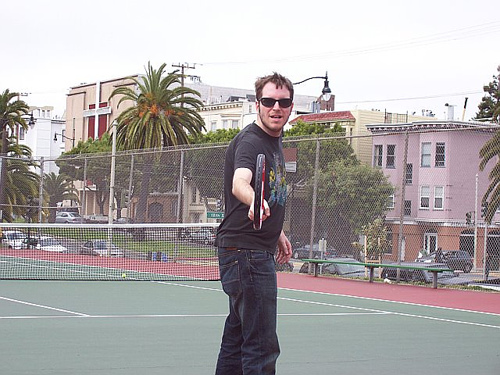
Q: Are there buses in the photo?
A: No, there are no buses.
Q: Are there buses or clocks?
A: No, there are no buses or clocks.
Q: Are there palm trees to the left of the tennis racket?
A: Yes, there is a palm tree to the left of the tennis racket.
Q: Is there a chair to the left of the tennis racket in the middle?
A: No, there is a palm tree to the left of the tennis racket.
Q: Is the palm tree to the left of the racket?
A: Yes, the palm tree is to the left of the racket.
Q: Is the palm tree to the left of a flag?
A: No, the palm tree is to the left of the racket.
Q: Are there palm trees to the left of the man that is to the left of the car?
A: Yes, there is a palm tree to the left of the man.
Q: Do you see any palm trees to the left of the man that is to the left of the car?
A: Yes, there is a palm tree to the left of the man.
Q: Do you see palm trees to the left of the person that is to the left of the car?
A: Yes, there is a palm tree to the left of the man.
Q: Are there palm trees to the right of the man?
A: No, the palm tree is to the left of the man.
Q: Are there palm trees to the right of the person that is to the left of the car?
A: No, the palm tree is to the left of the man.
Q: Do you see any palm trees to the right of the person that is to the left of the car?
A: No, the palm tree is to the left of the man.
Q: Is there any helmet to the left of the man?
A: No, there is a palm tree to the left of the man.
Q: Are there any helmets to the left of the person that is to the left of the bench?
A: No, there is a palm tree to the left of the man.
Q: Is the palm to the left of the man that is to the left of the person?
A: Yes, the palm is to the left of the man.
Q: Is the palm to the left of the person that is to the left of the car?
A: Yes, the palm is to the left of the man.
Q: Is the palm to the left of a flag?
A: No, the palm is to the left of the man.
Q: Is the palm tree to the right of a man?
A: No, the palm tree is to the left of a man.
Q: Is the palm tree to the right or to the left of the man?
A: The palm tree is to the left of the man.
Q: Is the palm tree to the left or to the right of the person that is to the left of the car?
A: The palm tree is to the left of the man.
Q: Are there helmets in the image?
A: No, there are no helmets.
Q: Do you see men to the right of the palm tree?
A: Yes, there is a man to the right of the palm tree.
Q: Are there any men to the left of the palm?
A: No, the man is to the right of the palm.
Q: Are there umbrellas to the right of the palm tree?
A: No, there is a man to the right of the palm tree.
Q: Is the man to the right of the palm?
A: Yes, the man is to the right of the palm.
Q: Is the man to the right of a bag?
A: No, the man is to the right of the palm.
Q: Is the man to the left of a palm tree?
A: No, the man is to the right of a palm tree.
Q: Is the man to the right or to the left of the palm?
A: The man is to the right of the palm.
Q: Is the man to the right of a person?
A: No, the man is to the left of a person.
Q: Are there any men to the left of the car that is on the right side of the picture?
A: Yes, there is a man to the left of the car.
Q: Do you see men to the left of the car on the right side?
A: Yes, there is a man to the left of the car.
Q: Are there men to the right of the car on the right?
A: No, the man is to the left of the car.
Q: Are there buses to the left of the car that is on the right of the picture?
A: No, there is a man to the left of the car.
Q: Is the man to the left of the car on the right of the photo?
A: Yes, the man is to the left of the car.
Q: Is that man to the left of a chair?
A: No, the man is to the left of the car.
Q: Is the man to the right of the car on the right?
A: No, the man is to the left of the car.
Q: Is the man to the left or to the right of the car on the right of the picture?
A: The man is to the left of the car.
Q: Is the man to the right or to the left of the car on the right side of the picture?
A: The man is to the left of the car.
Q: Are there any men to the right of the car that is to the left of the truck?
A: No, the man is to the left of the car.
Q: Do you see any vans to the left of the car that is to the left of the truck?
A: No, there is a man to the left of the car.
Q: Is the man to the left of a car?
A: Yes, the man is to the left of a car.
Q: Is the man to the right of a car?
A: No, the man is to the left of a car.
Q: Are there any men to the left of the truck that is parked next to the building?
A: Yes, there is a man to the left of the truck.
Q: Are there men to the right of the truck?
A: No, the man is to the left of the truck.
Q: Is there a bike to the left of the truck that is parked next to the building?
A: No, there is a man to the left of the truck.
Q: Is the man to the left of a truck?
A: Yes, the man is to the left of a truck.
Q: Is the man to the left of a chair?
A: No, the man is to the left of a truck.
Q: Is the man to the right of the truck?
A: No, the man is to the left of the truck.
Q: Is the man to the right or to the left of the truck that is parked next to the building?
A: The man is to the left of the truck.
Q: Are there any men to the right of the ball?
A: Yes, there is a man to the right of the ball.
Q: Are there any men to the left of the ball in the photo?
A: No, the man is to the right of the ball.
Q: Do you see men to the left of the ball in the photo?
A: No, the man is to the right of the ball.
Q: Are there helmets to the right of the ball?
A: No, there is a man to the right of the ball.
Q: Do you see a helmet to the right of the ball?
A: No, there is a man to the right of the ball.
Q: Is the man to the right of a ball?
A: Yes, the man is to the right of a ball.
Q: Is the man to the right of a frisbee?
A: No, the man is to the right of a ball.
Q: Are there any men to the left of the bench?
A: Yes, there is a man to the left of the bench.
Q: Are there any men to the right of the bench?
A: No, the man is to the left of the bench.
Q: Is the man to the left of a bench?
A: Yes, the man is to the left of a bench.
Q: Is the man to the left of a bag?
A: No, the man is to the left of a bench.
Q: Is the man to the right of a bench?
A: No, the man is to the left of a bench.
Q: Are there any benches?
A: Yes, there is a bench.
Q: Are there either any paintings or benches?
A: Yes, there is a bench.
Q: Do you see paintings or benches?
A: Yes, there is a bench.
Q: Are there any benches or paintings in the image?
A: Yes, there is a bench.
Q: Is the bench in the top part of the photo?
A: No, the bench is in the bottom of the image.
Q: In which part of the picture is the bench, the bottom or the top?
A: The bench is in the bottom of the image.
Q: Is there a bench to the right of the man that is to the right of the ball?
A: Yes, there is a bench to the right of the man.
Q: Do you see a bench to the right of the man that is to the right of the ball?
A: Yes, there is a bench to the right of the man.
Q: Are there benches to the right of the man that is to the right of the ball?
A: Yes, there is a bench to the right of the man.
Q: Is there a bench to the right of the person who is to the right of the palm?
A: Yes, there is a bench to the right of the man.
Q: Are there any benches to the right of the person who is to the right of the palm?
A: Yes, there is a bench to the right of the man.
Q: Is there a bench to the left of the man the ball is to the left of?
A: No, the bench is to the right of the man.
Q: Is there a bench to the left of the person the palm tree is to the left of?
A: No, the bench is to the right of the man.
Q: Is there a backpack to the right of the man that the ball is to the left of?
A: No, there is a bench to the right of the man.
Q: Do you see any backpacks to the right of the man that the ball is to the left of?
A: No, there is a bench to the right of the man.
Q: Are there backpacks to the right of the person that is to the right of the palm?
A: No, there is a bench to the right of the man.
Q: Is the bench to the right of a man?
A: Yes, the bench is to the right of a man.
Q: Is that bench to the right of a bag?
A: No, the bench is to the right of a man.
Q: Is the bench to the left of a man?
A: No, the bench is to the right of a man.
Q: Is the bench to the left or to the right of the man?
A: The bench is to the right of the man.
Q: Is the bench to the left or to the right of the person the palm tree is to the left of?
A: The bench is to the right of the man.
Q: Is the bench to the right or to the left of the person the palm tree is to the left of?
A: The bench is to the right of the man.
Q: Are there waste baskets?
A: No, there are no waste baskets.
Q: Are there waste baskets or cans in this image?
A: No, there are no waste baskets or cans.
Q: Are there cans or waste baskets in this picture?
A: No, there are no waste baskets or cans.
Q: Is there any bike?
A: No, there are no bikes.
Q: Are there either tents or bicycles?
A: No, there are no bicycles or tents.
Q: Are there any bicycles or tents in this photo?
A: No, there are no bicycles or tents.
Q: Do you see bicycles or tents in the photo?
A: No, there are no bicycles or tents.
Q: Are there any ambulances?
A: No, there are no ambulances.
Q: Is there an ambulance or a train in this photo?
A: No, there are no ambulances or trains.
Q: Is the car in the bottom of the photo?
A: Yes, the car is in the bottom of the image.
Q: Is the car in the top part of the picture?
A: No, the car is in the bottom of the image.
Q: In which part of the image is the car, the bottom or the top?
A: The car is in the bottom of the image.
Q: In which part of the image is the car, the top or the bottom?
A: The car is in the bottom of the image.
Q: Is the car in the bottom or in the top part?
A: The car is in the bottom of the image.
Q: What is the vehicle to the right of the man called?
A: The vehicle is a car.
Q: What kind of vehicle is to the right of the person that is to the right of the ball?
A: The vehicle is a car.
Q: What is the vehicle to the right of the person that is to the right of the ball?
A: The vehicle is a car.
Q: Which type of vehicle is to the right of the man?
A: The vehicle is a car.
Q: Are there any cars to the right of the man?
A: Yes, there is a car to the right of the man.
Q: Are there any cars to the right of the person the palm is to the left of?
A: Yes, there is a car to the right of the man.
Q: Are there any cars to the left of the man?
A: No, the car is to the right of the man.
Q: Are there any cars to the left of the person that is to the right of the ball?
A: No, the car is to the right of the man.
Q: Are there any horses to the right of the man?
A: No, there is a car to the right of the man.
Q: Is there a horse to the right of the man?
A: No, there is a car to the right of the man.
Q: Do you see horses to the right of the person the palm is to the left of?
A: No, there is a car to the right of the man.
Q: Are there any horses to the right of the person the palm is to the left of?
A: No, there is a car to the right of the man.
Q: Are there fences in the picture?
A: Yes, there is a fence.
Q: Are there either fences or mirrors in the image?
A: Yes, there is a fence.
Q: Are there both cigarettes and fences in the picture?
A: No, there is a fence but no cigarettes.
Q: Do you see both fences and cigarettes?
A: No, there is a fence but no cigarettes.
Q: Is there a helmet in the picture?
A: No, there are no helmets.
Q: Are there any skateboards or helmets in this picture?
A: No, there are no helmets or skateboards.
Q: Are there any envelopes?
A: No, there are no envelopes.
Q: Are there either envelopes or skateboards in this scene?
A: No, there are no envelopes or skateboards.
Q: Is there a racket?
A: Yes, there is a racket.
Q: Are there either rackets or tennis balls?
A: Yes, there is a racket.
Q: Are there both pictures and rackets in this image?
A: No, there is a racket but no pictures.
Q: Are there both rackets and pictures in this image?
A: No, there is a racket but no pictures.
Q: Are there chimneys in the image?
A: No, there are no chimneys.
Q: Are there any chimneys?
A: No, there are no chimneys.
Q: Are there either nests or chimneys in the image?
A: No, there are no chimneys or nests.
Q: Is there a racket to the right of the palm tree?
A: Yes, there is a racket to the right of the palm tree.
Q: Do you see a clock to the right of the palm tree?
A: No, there is a racket to the right of the palm tree.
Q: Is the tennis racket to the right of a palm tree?
A: Yes, the tennis racket is to the right of a palm tree.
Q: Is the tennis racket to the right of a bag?
A: No, the tennis racket is to the right of a palm tree.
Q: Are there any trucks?
A: Yes, there is a truck.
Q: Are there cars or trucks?
A: Yes, there is a truck.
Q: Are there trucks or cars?
A: Yes, there is a truck.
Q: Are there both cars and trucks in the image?
A: Yes, there are both a truck and a car.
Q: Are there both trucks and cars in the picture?
A: Yes, there are both a truck and a car.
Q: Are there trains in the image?
A: No, there are no trains.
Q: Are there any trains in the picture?
A: No, there are no trains.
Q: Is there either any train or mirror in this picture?
A: No, there are no trains or mirrors.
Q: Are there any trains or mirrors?
A: No, there are no trains or mirrors.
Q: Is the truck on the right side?
A: Yes, the truck is on the right of the image.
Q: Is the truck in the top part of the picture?
A: No, the truck is in the bottom of the image.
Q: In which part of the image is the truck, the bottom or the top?
A: The truck is in the bottom of the image.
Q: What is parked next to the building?
A: The truck is parked next to the building.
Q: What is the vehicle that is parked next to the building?
A: The vehicle is a truck.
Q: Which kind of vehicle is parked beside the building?
A: The vehicle is a truck.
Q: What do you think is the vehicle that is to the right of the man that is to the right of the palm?
A: The vehicle is a truck.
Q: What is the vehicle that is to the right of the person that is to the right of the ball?
A: The vehicle is a truck.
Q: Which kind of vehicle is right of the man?
A: The vehicle is a truck.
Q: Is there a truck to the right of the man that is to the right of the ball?
A: Yes, there is a truck to the right of the man.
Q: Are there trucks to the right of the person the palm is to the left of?
A: Yes, there is a truck to the right of the man.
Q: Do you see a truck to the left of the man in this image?
A: No, the truck is to the right of the man.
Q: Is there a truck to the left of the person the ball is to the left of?
A: No, the truck is to the right of the man.